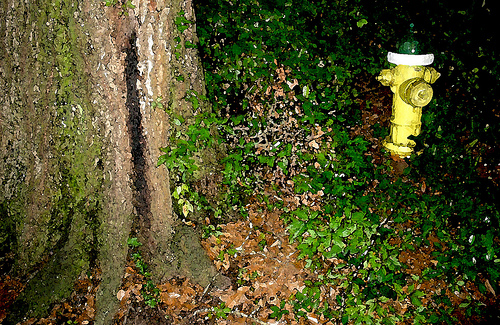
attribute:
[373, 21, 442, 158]
hydrant — yellow, dirty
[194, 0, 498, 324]
leaves — green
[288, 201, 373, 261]
bush — small, green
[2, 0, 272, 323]
tree — brown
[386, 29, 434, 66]
top — green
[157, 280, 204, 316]
leaves — dead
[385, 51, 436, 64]
stripe — white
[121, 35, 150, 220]
stripe — dark